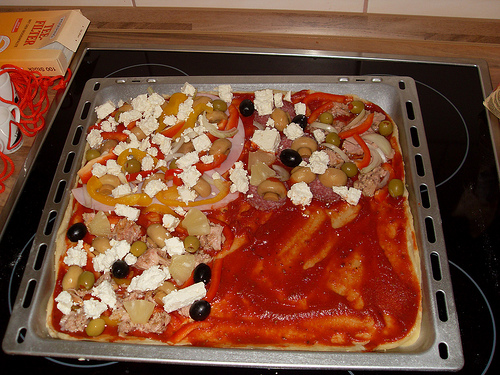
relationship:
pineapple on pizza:
[122, 298, 159, 323] [62, 79, 440, 349]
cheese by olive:
[84, 242, 141, 294] [178, 298, 216, 323]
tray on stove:
[8, 73, 462, 367] [0, 48, 493, 370]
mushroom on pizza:
[253, 179, 303, 210] [41, 82, 428, 356]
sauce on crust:
[230, 214, 426, 344] [222, 208, 423, 345]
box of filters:
[3, 11, 91, 81] [40, 7, 82, 67]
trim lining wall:
[1, 5, 499, 90] [1, 0, 499, 90]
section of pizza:
[217, 199, 423, 356] [236, 195, 417, 354]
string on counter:
[0, 62, 71, 197] [0, 7, 497, 214]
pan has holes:
[398, 94, 459, 319] [395, 78, 465, 351]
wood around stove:
[2, 6, 483, 74] [348, 14, 473, 126]